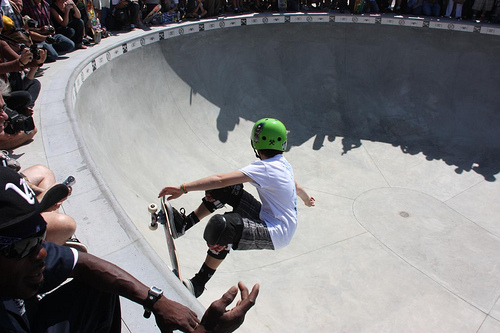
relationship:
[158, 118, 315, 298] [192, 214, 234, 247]
boy wearing pads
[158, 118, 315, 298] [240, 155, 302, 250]
boy wearing t-shirt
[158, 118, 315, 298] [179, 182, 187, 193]
boy wearing bracelets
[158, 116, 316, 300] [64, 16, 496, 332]
boy skating skate bowl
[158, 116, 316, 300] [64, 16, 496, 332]
boy skateboarding in skate bowl